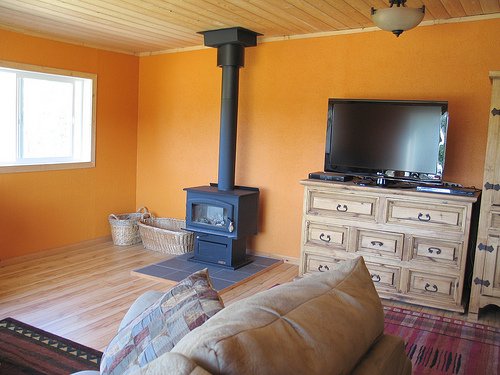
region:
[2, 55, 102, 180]
sliding window in orange wall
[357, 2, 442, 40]
light fixture on ceiling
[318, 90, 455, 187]
flat screen tv on top of dresser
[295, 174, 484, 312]
light brown wooden dresser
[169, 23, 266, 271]
black wood burning stove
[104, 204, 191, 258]
baskets near stove for firewood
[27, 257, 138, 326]
light wood floor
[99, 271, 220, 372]
patchwork throw pillow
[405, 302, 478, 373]
red and black woven rug near dresser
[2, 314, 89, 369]
woven rug, red and black, in front of couch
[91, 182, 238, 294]
two brown baskets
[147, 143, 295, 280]
a black woodstove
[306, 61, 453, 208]
a black flatscreen tv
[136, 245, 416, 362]
a brown couch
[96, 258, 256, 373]
a multicolored pillow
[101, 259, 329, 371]
a multi colored pillow on a couch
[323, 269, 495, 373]
a rug in a living room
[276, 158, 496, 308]
a wooden dresser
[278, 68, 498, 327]
a tv on a wooden dresser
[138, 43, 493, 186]
orange walls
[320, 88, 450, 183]
large flat screen tv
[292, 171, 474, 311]
brown dresser with multiple drawers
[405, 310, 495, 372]
red and black area rug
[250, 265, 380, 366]
tan pillow couch cushion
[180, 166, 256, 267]
black wood burning stove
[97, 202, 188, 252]
two wicker baskets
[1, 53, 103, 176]
partially open white window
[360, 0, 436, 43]
ceiling light fixture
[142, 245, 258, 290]
fireproof stone tiles under stove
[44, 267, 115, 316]
light tan wood floor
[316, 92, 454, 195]
Large black flat screen tv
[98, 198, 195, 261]
Two wicker baskets on the floor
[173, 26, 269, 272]
Black fireplace with large pipe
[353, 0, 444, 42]
Light hanging from the ceiling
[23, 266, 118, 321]
Light brown hardwood floors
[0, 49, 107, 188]
Rectangle shaped window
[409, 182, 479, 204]
Black box on the dresser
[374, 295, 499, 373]
Large rug on the floor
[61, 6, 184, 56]
Wood panels on ceiling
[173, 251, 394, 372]
Large tan colored pillow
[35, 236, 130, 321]
the floor is wooden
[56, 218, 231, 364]
the floor is wooden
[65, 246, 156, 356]
the floor is wooden